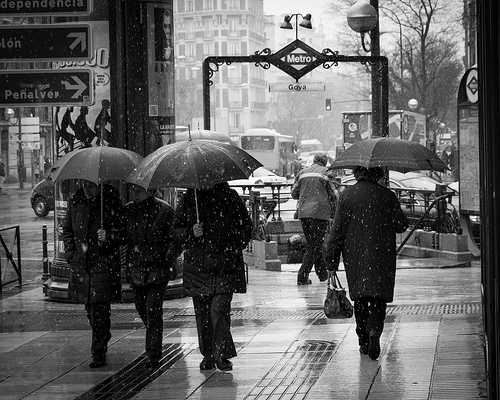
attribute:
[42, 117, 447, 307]
people — walking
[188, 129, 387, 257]
people — walking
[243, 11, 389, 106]
sign — black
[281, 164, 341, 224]
jacket — white, lined